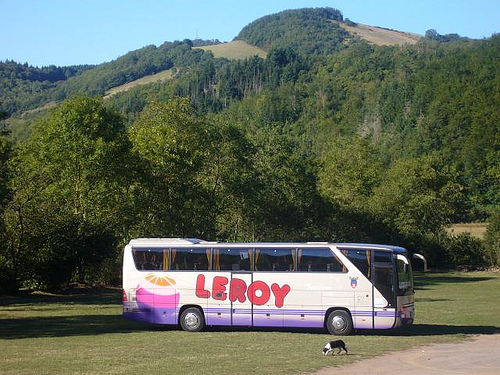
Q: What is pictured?
A: A passenger bus.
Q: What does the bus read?
A: Leroy.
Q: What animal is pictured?
A: A black and white dog.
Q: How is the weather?
A: Sunny.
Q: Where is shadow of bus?
A: On grass.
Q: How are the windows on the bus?
A: Wall of windows.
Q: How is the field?
A: Grassy field by trees.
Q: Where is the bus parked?
A: On the grass.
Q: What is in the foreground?
A: Bus.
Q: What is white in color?
A: Bus.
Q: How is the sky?
A: Clear.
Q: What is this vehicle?
A: Bus.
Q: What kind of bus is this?
A: Passenger.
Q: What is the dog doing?
A: Sniffing the ground.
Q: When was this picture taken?
A: During the day.